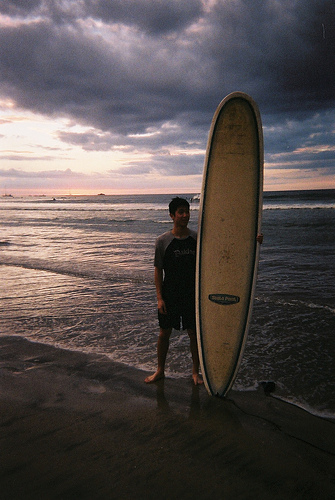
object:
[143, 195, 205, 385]
man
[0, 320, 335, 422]
sea foam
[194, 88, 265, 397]
board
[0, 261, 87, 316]
light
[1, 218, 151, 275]
reflection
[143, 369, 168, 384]
bare feet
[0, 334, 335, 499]
sand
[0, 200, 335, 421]
ocean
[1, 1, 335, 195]
sky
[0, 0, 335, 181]
cloud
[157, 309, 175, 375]
leg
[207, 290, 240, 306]
logo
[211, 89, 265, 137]
top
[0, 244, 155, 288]
wave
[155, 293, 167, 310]
hand